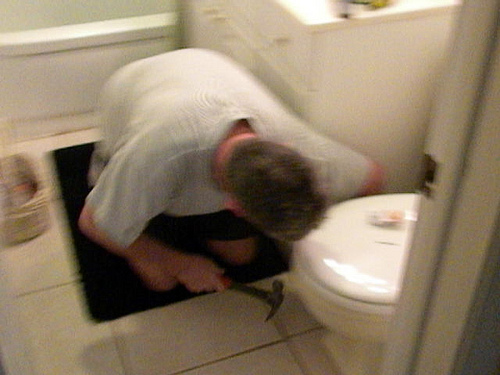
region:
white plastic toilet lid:
[316, 190, 421, 303]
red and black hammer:
[206, 268, 288, 318]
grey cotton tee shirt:
[93, 45, 336, 240]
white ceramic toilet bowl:
[291, 263, 385, 374]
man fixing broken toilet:
[83, 48, 377, 292]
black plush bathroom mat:
[48, 135, 289, 322]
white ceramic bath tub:
[0, 1, 185, 138]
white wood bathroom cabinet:
[193, 3, 451, 197]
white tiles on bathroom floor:
[1, 133, 327, 373]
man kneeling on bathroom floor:
[83, 53, 363, 313]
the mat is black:
[80, 264, 164, 341]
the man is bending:
[98, 41, 372, 350]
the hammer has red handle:
[215, 267, 300, 327]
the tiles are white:
[152, 326, 272, 366]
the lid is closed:
[340, 225, 415, 308]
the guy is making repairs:
[29, 29, 344, 305]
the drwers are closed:
[266, 8, 378, 75]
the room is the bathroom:
[6, 6, 498, 373]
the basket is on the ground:
[2, 150, 53, 253]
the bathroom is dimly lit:
[1, 4, 498, 374]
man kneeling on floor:
[74, 40, 381, 340]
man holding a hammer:
[78, 45, 378, 331]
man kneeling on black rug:
[78, 43, 386, 328]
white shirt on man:
[74, 46, 367, 241]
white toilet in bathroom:
[296, 185, 428, 371]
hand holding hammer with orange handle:
[176, 252, 290, 336]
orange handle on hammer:
[215, 274, 233, 294]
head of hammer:
[264, 280, 291, 325]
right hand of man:
[162, 245, 224, 300]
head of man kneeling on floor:
[204, 126, 328, 243]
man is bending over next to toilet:
[89, 50, 354, 215]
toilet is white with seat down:
[308, 150, 494, 315]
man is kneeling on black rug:
[35, 141, 237, 299]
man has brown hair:
[225, 130, 342, 221]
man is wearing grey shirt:
[54, 50, 273, 237]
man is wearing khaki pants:
[75, 49, 195, 186]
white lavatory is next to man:
[274, 2, 420, 144]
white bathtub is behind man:
[5, 1, 125, 98]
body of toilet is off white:
[278, 255, 395, 372]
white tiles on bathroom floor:
[20, 247, 303, 374]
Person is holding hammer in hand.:
[198, 263, 292, 327]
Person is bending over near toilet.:
[228, 154, 383, 357]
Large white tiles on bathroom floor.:
[55, 316, 242, 373]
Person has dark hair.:
[249, 140, 324, 211]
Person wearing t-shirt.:
[110, 77, 200, 178]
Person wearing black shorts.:
[174, 212, 236, 249]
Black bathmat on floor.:
[46, 131, 226, 346]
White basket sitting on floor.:
[5, 141, 87, 258]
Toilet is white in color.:
[291, 177, 433, 344]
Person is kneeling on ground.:
[123, 200, 277, 298]